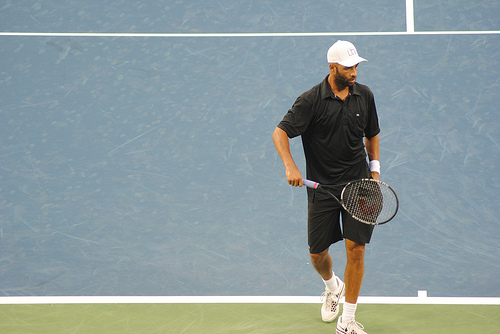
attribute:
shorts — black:
[306, 179, 379, 253]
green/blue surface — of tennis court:
[1, 233, 273, 328]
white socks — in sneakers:
[321, 271, 360, 322]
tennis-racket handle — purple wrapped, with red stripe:
[302, 178, 321, 189]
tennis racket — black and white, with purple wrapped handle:
[292, 174, 402, 225]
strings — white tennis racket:
[339, 181, 397, 221]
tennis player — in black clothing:
[268, 37, 386, 332]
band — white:
[366, 156, 380, 174]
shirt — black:
[275, 74, 386, 188]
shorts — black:
[298, 169, 372, 257]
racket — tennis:
[291, 175, 402, 231]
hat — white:
[324, 38, 367, 73]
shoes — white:
[315, 273, 349, 324]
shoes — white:
[326, 314, 369, 333]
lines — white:
[2, 294, 498, 310]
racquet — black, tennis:
[288, 171, 401, 226]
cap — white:
[322, 37, 366, 67]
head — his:
[326, 37, 368, 86]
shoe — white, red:
[314, 279, 344, 321]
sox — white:
[320, 272, 341, 291]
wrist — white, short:
[372, 161, 381, 174]